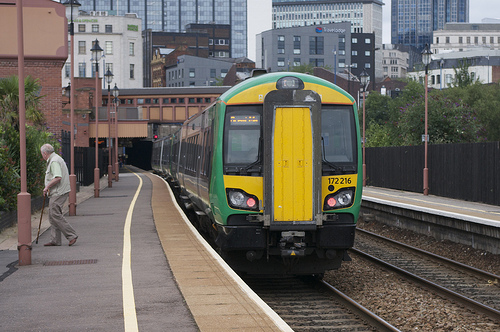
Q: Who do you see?
A: A man.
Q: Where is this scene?
A: A train station.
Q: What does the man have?
A: A walking cane.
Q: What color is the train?
A: Green and yellow.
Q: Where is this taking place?
A: In the city.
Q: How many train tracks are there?
A: Two.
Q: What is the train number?
A: 172216.